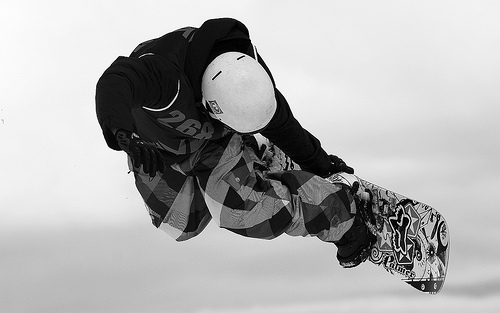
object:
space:
[209, 70, 223, 80]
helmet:
[201, 50, 278, 135]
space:
[237, 53, 247, 61]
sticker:
[207, 99, 223, 116]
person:
[96, 17, 377, 269]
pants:
[128, 133, 357, 244]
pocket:
[223, 165, 256, 203]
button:
[235, 176, 242, 183]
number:
[157, 108, 214, 143]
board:
[355, 175, 451, 296]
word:
[383, 254, 416, 280]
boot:
[337, 181, 376, 269]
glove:
[116, 130, 169, 177]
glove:
[328, 152, 357, 176]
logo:
[386, 205, 412, 258]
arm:
[95, 53, 170, 138]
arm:
[262, 82, 331, 176]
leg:
[200, 132, 353, 240]